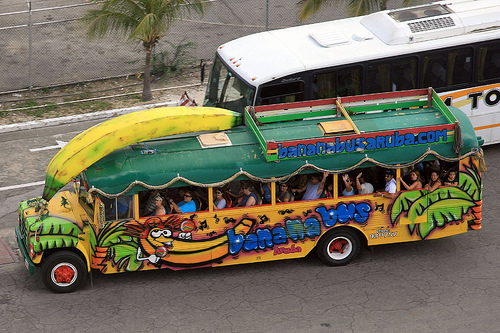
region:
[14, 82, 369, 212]
Large banana on the bus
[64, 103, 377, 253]
Tour bus in Aruba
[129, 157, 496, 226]
People on the tour bus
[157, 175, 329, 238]
Tourists on vacation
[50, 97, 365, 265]
Large banana tour bus on the road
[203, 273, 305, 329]
Crack asphalt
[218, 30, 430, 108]
White tour bus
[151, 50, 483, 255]
Two buses on the roadway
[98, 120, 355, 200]
Bus with a green roof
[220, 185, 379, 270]
Banana bus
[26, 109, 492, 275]
Tour bus with banana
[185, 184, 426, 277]
Banana bus tour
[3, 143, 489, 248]
People riding on the bus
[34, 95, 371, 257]
Large banana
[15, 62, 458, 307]
Large tour bus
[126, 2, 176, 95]
Palm tree on the street side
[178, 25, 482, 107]
White tour bus next to the banana bus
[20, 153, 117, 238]
Lizard on the hood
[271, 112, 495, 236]
Aruba bus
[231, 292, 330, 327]
Cracked asphalt on the roadway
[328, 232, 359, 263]
part of a rear wheel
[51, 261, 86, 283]
part of a front wheels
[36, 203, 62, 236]
bonnet of the bus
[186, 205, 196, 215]
part of a blue top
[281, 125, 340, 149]
top of a bus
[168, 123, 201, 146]
part of a banana statue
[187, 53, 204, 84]
side mirror of the white bus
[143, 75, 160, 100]
stem of a palmtree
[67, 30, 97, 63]
part of a meshed fence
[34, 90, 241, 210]
A large yellow banana.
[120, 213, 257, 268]
A banana painted on the side of a bus.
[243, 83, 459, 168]
A cargo hold for the yellow bus.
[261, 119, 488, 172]
A website address on the side of a bus.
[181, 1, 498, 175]
A white bus next to the yellow bus.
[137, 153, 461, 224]
A group of people riding the banana bus.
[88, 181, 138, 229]
The bus driver for the banana bus.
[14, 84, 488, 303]
A large yellow bus with cartoons painted on it.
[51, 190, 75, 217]
A small plastic lizard on the hood of the bus.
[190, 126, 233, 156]
The top hatch for the banana bus.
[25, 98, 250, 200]
The banana on top of the roof of the bus.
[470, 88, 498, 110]
The letters TO on the white bus.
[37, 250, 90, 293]
The front wheel of the banana bus.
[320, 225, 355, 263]
The back wheel of the banana bus.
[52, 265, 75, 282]
The red hubcap on the front wheel of the banana bus.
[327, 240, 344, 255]
The red hubcap on the back wheel of the banana bus.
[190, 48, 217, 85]
The side view mirror on the white bus.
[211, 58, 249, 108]
The windshield window of the white bus.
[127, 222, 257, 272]
The banana painted on the side of the bus.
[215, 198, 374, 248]
The blue letters on the banana bus.